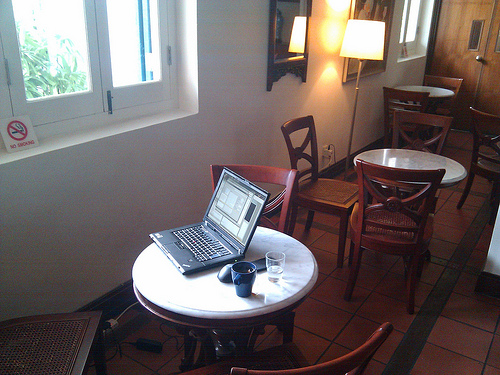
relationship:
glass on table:
[266, 251, 286, 281] [131, 226, 318, 371]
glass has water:
[266, 251, 286, 281] [269, 267, 282, 280]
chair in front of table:
[178, 323, 392, 374] [131, 226, 318, 371]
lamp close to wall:
[338, 18, 386, 176] [4, 0, 434, 320]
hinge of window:
[167, 45, 173, 64] [0, 0, 178, 140]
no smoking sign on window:
[1, 115, 39, 158] [0, 0, 178, 140]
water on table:
[269, 267, 282, 280] [131, 226, 318, 371]